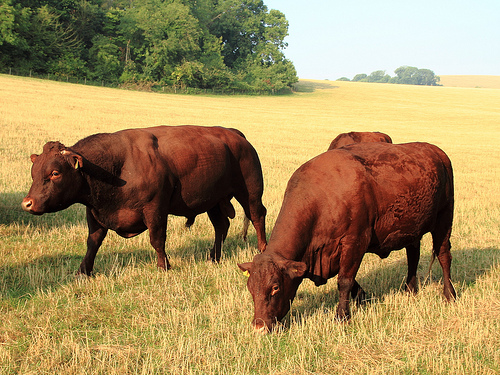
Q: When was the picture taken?
A: Daytime.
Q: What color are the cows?
A: Brown.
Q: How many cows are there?
A: Three.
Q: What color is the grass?
A: Yellow.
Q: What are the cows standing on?
A: Grass.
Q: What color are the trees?
A: Green.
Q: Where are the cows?
A: On the gras.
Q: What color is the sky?
A: Blue.